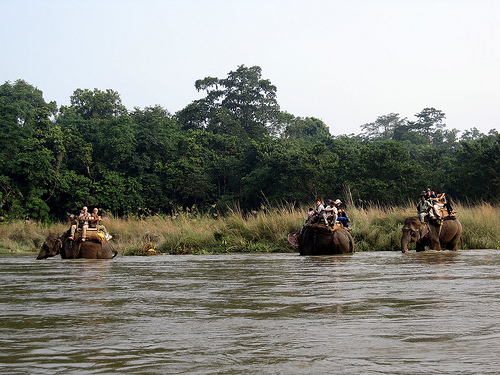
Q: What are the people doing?
A: Riding.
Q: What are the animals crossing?
A: Water.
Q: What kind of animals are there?
A: Elephant.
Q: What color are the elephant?
A: Gray.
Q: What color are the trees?
A: Green.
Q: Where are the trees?
A: On bank.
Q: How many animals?
A: Three.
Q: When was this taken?
A: Day time.